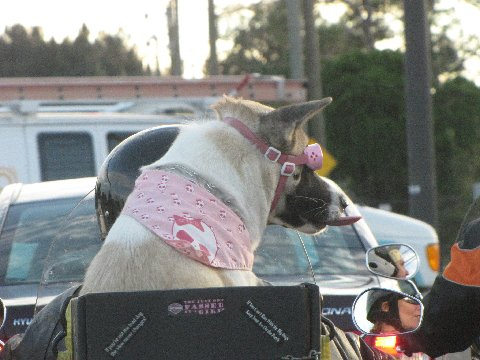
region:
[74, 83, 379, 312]
a dog riding on a motorcycle.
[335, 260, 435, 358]
a side view mirror.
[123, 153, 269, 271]
a pink scarf on a dog.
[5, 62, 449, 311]
a parked white van.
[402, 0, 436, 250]
a tall pole near a parking lot.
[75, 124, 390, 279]
a wind shield on a motorcycle.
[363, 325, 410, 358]
a right blinker on a motorcycle.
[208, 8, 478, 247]
a large tree near a parked car.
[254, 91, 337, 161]
a right dog ear.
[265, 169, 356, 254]
a mouth on a dog.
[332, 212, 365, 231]
dogs tongue sticking out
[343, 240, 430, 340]
motorcycle side mirrors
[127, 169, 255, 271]
pink bandana on the dog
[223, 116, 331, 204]
pink goggles on the dog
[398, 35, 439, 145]
brown utility pole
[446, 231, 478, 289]
orange stripe on jacket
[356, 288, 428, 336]
reflection of face in the side mirror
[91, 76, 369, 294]
white dog on a motorcycle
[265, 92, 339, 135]
ear of the dog on the motorcycle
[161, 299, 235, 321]
sticker on the back of the motorcycle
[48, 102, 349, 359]
an animal by the car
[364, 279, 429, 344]
a head in the mirror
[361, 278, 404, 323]
she is wearing a helmet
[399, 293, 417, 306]
she is wearing glasses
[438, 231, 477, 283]
an orange strip of fabric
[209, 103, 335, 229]
the animal is wearing a pink harness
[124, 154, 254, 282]
the animal has a fabric collar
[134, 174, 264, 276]
the collar is pink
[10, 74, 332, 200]
a van behind the animal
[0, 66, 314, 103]
a ladder on the van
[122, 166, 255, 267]
dog wearing a pink bandana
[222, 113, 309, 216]
pink straps on dog's head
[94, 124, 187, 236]
black shiny helmet behind dog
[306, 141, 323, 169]
dog wearing pink goggles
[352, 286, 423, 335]
mirror to the right of dog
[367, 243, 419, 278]
mirror above mirror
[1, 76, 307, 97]
long ladder on top of van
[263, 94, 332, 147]
brown pointy ear on dog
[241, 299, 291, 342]
sticker on seat back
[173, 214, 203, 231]
pink bow on bandana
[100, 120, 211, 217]
Person is wearing a helmet.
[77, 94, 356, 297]
Dog on the bike.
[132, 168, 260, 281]
The scarf is pink.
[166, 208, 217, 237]
Bow on the skull.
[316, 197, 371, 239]
Tongue is out.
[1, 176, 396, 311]
Car in front of the bike.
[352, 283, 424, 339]
Mirror on the bike.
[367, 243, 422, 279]
Mirror of the other bike.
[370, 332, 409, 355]
Light on the car is on.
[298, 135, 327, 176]
Glasses on the dog.